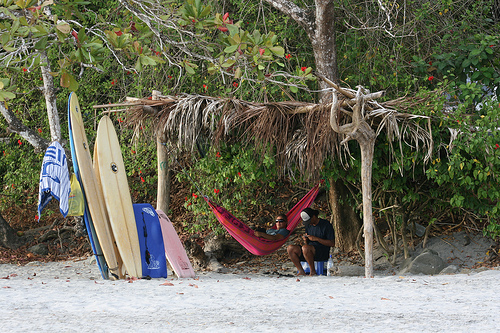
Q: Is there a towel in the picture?
A: Yes, there is a towel.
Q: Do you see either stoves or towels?
A: Yes, there is a towel.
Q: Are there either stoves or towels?
A: Yes, there is a towel.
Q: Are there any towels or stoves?
A: Yes, there is a towel.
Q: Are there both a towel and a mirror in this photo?
A: No, there is a towel but no mirrors.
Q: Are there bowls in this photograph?
A: No, there are no bowls.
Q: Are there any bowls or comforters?
A: No, there are no bowls or comforters.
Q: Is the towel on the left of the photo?
A: Yes, the towel is on the left of the image.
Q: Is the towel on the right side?
A: No, the towel is on the left of the image.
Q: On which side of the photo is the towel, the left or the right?
A: The towel is on the left of the image.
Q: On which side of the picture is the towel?
A: The towel is on the left of the image.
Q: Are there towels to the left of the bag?
A: Yes, there is a towel to the left of the bag.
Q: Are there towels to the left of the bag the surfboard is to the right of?
A: Yes, there is a towel to the left of the bag.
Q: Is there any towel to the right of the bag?
A: No, the towel is to the left of the bag.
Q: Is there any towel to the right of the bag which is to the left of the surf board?
A: No, the towel is to the left of the bag.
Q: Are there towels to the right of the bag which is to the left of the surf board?
A: No, the towel is to the left of the bag.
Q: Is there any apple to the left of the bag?
A: No, there is a towel to the left of the bag.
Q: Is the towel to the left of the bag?
A: Yes, the towel is to the left of the bag.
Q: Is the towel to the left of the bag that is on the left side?
A: Yes, the towel is to the left of the bag.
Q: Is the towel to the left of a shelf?
A: No, the towel is to the left of the bag.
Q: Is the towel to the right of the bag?
A: No, the towel is to the left of the bag.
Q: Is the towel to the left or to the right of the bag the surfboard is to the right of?
A: The towel is to the left of the bag.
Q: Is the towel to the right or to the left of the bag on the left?
A: The towel is to the left of the bag.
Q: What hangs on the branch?
A: The towel hangs on the branch.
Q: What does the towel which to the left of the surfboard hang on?
A: The towel hangs on the branch.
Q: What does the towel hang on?
A: The towel hangs on the branch.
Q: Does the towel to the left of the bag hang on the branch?
A: Yes, the towel hangs on the branch.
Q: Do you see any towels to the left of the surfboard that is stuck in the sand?
A: Yes, there is a towel to the left of the surfboard.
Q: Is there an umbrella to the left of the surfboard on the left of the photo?
A: No, there is a towel to the left of the surf board.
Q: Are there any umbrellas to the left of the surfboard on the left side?
A: No, there is a towel to the left of the surf board.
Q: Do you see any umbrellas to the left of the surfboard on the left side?
A: No, there is a towel to the left of the surf board.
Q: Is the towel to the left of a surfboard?
A: Yes, the towel is to the left of a surfboard.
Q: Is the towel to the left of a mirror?
A: No, the towel is to the left of a surfboard.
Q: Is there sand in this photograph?
A: Yes, there is sand.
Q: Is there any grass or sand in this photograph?
A: Yes, there is sand.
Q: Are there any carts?
A: No, there are no carts.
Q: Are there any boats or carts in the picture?
A: No, there are no carts or boats.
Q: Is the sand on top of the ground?
A: Yes, the sand is on top of the ground.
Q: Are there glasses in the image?
A: No, there are no glasses.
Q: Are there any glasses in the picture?
A: No, there are no glasses.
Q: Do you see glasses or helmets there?
A: No, there are no glasses or helmets.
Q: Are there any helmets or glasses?
A: No, there are no glasses or helmets.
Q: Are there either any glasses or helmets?
A: No, there are no glasses or helmets.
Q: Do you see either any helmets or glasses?
A: No, there are no glasses or helmets.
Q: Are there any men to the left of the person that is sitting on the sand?
A: Yes, there is a man to the left of the person.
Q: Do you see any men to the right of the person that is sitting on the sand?
A: No, the man is to the left of the person.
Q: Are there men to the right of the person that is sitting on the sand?
A: No, the man is to the left of the person.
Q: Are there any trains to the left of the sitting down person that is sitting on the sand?
A: No, there is a man to the left of the person.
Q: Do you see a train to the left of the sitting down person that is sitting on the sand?
A: No, there is a man to the left of the person.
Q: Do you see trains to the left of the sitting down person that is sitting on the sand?
A: No, there is a man to the left of the person.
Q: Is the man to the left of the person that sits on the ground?
A: Yes, the man is to the left of the person.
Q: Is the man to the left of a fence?
A: No, the man is to the left of the person.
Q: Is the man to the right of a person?
A: No, the man is to the left of a person.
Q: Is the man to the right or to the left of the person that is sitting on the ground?
A: The man is to the left of the person.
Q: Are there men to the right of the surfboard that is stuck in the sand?
A: Yes, there is a man to the right of the surfboard.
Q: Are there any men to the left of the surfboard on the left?
A: No, the man is to the right of the surfboard.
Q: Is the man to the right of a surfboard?
A: Yes, the man is to the right of a surfboard.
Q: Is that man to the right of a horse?
A: No, the man is to the right of a surfboard.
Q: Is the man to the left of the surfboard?
A: No, the man is to the right of the surfboard.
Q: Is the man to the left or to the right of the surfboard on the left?
A: The man is to the right of the surfboard.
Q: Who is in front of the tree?
A: The man is in front of the tree.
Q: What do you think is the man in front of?
A: The man is in front of the tree.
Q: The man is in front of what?
A: The man is in front of the tree.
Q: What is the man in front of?
A: The man is in front of the tree.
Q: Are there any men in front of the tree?
A: Yes, there is a man in front of the tree.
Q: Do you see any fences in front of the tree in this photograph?
A: No, there is a man in front of the tree.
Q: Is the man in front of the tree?
A: Yes, the man is in front of the tree.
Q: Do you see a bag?
A: Yes, there is a bag.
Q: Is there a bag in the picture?
A: Yes, there is a bag.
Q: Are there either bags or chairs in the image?
A: Yes, there is a bag.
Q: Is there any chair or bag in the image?
A: Yes, there is a bag.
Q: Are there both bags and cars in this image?
A: No, there is a bag but no cars.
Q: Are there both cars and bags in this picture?
A: No, there is a bag but no cars.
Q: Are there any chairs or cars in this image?
A: No, there are no cars or chairs.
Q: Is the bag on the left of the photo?
A: Yes, the bag is on the left of the image.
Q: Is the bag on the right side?
A: No, the bag is on the left of the image.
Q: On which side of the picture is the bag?
A: The bag is on the left of the image.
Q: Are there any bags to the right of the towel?
A: Yes, there is a bag to the right of the towel.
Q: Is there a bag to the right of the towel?
A: Yes, there is a bag to the right of the towel.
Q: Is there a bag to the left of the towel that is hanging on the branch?
A: No, the bag is to the right of the towel.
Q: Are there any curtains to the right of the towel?
A: No, there is a bag to the right of the towel.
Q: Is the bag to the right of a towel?
A: Yes, the bag is to the right of a towel.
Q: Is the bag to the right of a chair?
A: No, the bag is to the right of a towel.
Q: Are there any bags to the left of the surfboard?
A: Yes, there is a bag to the left of the surfboard.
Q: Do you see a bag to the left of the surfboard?
A: Yes, there is a bag to the left of the surfboard.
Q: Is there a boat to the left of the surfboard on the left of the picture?
A: No, there is a bag to the left of the surfboard.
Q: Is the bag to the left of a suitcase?
A: No, the bag is to the left of the surfboard.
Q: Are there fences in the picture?
A: No, there are no fences.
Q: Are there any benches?
A: No, there are no benches.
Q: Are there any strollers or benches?
A: No, there are no benches or strollers.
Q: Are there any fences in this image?
A: No, there are no fences.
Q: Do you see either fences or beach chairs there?
A: No, there are no fences or beach chairs.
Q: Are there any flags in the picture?
A: No, there are no flags.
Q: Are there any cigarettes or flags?
A: No, there are no flags or cigarettes.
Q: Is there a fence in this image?
A: No, there are no fences.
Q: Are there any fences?
A: No, there are no fences.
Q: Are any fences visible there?
A: No, there are no fences.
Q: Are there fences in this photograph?
A: No, there are no fences.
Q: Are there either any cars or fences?
A: No, there are no fences or cars.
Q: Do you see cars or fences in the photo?
A: No, there are no fences or cars.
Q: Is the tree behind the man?
A: Yes, the tree is behind the man.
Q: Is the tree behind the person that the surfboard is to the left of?
A: Yes, the tree is behind the man.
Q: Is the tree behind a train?
A: No, the tree is behind the man.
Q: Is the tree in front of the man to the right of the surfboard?
A: No, the tree is behind the man.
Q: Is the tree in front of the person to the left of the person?
A: No, the tree is behind the man.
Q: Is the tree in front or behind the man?
A: The tree is behind the man.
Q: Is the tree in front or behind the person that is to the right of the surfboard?
A: The tree is behind the man.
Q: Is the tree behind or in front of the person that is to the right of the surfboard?
A: The tree is behind the man.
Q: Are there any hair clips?
A: No, there are no hair clips.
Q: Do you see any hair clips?
A: No, there are no hair clips.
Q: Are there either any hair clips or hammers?
A: No, there are no hair clips or hammers.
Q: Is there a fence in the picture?
A: No, there are no fences.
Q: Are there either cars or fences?
A: No, there are no fences or cars.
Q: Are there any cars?
A: No, there are no cars.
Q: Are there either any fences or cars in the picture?
A: No, there are no cars or fences.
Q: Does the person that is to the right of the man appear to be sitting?
A: Yes, the person is sitting.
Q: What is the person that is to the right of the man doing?
A: The person is sitting.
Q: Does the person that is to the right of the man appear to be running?
A: No, the person is sitting.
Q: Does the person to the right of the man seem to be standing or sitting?
A: The person is sitting.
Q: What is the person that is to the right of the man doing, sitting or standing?
A: The person is sitting.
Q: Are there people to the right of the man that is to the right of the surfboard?
A: Yes, there is a person to the right of the man.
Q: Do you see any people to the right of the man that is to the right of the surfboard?
A: Yes, there is a person to the right of the man.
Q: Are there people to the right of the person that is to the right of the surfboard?
A: Yes, there is a person to the right of the man.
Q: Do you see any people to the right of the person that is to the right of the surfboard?
A: Yes, there is a person to the right of the man.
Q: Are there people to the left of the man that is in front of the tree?
A: No, the person is to the right of the man.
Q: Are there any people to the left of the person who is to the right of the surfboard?
A: No, the person is to the right of the man.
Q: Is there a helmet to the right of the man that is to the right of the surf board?
A: No, there is a person to the right of the man.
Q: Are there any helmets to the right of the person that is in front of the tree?
A: No, there is a person to the right of the man.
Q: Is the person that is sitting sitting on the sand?
A: Yes, the person is sitting on the sand.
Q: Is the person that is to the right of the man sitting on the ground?
A: Yes, the person is sitting on the ground.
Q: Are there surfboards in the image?
A: Yes, there is a surfboard.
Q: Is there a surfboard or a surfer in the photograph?
A: Yes, there is a surfboard.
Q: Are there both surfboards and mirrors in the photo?
A: No, there is a surfboard but no mirrors.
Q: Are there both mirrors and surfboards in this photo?
A: No, there is a surfboard but no mirrors.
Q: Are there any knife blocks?
A: No, there are no knife blocks.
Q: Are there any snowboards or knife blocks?
A: No, there are no knife blocks or snowboards.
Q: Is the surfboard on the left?
A: Yes, the surfboard is on the left of the image.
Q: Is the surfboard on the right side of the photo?
A: No, the surfboard is on the left of the image.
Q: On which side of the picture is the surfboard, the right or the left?
A: The surfboard is on the left of the image.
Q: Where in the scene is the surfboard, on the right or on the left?
A: The surfboard is on the left of the image.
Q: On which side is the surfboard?
A: The surfboard is on the left of the image.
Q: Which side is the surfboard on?
A: The surfboard is on the left of the image.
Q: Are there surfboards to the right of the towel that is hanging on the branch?
A: Yes, there is a surfboard to the right of the towel.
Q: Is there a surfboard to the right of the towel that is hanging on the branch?
A: Yes, there is a surfboard to the right of the towel.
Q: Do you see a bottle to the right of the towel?
A: No, there is a surfboard to the right of the towel.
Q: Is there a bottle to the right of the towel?
A: No, there is a surfboard to the right of the towel.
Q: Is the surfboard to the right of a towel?
A: Yes, the surfboard is to the right of a towel.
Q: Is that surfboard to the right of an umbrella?
A: No, the surfboard is to the right of a towel.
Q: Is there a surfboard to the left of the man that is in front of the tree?
A: Yes, there is a surfboard to the left of the man.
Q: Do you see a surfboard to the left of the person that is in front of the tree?
A: Yes, there is a surfboard to the left of the man.